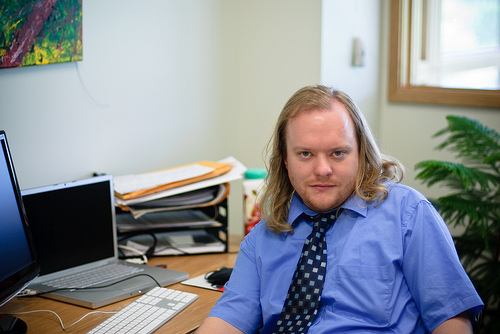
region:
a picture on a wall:
[0, 0, 84, 70]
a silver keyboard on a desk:
[21, 173, 190, 310]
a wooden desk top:
[2, 231, 244, 332]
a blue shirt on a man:
[210, 180, 482, 332]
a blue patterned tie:
[268, 207, 345, 332]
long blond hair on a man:
[262, 84, 402, 234]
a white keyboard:
[80, 285, 197, 333]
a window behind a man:
[378, 0, 499, 105]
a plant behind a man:
[414, 112, 498, 332]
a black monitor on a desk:
[2, 126, 39, 312]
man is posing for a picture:
[273, 98, 408, 324]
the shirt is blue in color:
[355, 206, 453, 332]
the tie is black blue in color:
[288, 225, 329, 331]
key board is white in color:
[104, 300, 193, 332]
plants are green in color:
[438, 124, 497, 215]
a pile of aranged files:
[143, 160, 243, 270]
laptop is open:
[34, 169, 139, 296]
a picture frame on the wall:
[6, 10, 82, 68]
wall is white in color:
[148, 39, 268, 98]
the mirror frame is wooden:
[374, 30, 461, 122]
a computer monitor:
[12, 170, 132, 278]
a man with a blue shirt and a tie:
[200, 72, 473, 321]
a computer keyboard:
[59, 272, 201, 329]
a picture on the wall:
[6, 10, 99, 72]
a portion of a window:
[389, 16, 497, 111]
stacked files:
[100, 150, 246, 266]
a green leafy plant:
[416, 113, 498, 228]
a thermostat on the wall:
[338, 27, 380, 69]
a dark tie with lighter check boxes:
[272, 212, 344, 325]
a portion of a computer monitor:
[2, 140, 47, 319]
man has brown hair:
[243, 65, 363, 191]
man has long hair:
[261, 83, 393, 220]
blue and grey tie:
[274, 208, 340, 330]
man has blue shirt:
[218, 188, 435, 331]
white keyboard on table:
[88, 278, 173, 330]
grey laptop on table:
[7, 174, 187, 306]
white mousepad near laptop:
[190, 265, 245, 302]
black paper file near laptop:
[110, 164, 233, 260]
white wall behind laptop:
[27, 63, 196, 186]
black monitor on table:
[1, 133, 33, 283]